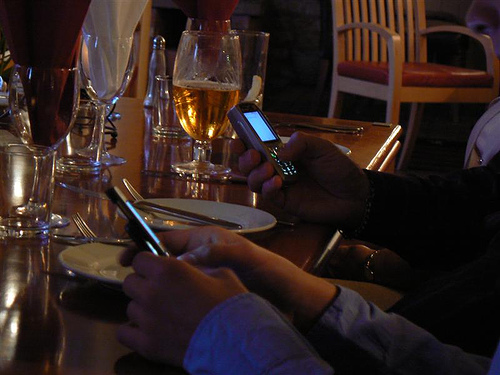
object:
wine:
[170, 82, 233, 148]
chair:
[322, 1, 494, 119]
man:
[228, 129, 500, 357]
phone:
[225, 99, 303, 187]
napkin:
[78, 0, 149, 102]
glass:
[72, 33, 140, 167]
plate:
[113, 191, 278, 239]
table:
[0, 101, 397, 374]